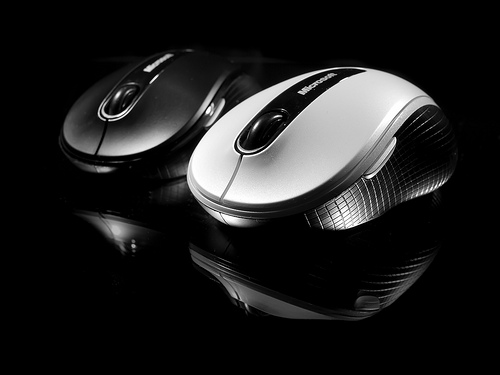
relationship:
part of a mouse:
[242, 108, 288, 145] [184, 51, 460, 236]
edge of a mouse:
[325, 98, 439, 190] [184, 51, 460, 236]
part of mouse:
[111, 84, 150, 100] [63, 43, 261, 174]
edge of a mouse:
[103, 124, 197, 176] [63, 43, 261, 174]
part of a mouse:
[361, 134, 408, 183] [184, 51, 460, 236]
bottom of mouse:
[199, 216, 434, 274] [184, 51, 460, 236]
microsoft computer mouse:
[288, 69, 343, 96] [184, 51, 460, 236]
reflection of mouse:
[192, 224, 445, 314] [184, 51, 460, 236]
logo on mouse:
[288, 69, 343, 96] [184, 51, 460, 236]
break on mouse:
[215, 150, 252, 199] [184, 51, 460, 236]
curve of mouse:
[303, 104, 461, 231] [184, 51, 460, 236]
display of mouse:
[63, 36, 459, 230] [184, 51, 460, 236]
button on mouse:
[365, 136, 401, 181] [184, 51, 460, 236]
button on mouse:
[201, 99, 229, 127] [63, 43, 261, 174]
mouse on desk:
[184, 51, 460, 236] [0, 0, 498, 374]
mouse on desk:
[63, 43, 261, 174] [4, 8, 491, 362]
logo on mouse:
[143, 51, 176, 74] [63, 43, 261, 174]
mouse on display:
[184, 51, 460, 236] [63, 36, 459, 230]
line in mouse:
[215, 150, 252, 199] [184, 51, 460, 236]